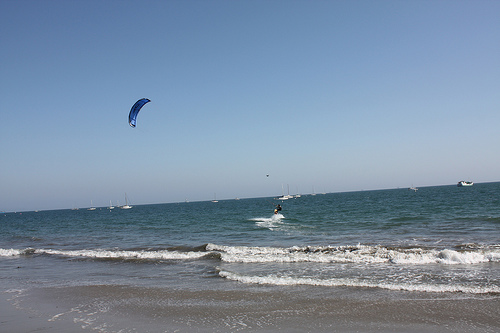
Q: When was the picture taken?
A: Daytime.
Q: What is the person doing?
A: Kitesurfing.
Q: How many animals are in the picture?
A: None.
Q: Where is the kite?
A: In the air.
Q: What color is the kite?
A: Blue.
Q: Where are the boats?
A: Behind the person.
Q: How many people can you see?
A: One.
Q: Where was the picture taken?
A: At the beach.